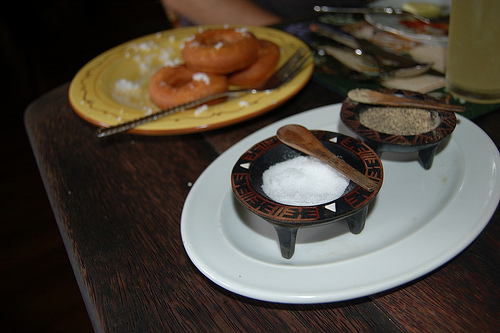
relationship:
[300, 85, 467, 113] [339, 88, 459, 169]
spoon on bowl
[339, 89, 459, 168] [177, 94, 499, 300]
bowl in plate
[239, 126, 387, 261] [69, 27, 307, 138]
bowl in plate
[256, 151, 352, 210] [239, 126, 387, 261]
salt in bowl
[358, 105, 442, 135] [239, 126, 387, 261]
pepper in bowl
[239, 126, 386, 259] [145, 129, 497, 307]
bowl sitting in plate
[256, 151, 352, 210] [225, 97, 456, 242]
salt sitting in bowl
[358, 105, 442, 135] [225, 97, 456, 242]
pepper sitting in bowl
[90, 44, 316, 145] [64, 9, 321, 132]
fork sitting in plate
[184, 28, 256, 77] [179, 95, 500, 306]
donut sitting in dish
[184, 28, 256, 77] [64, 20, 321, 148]
donut sitting in plate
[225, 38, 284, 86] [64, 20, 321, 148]
donut sitting in plate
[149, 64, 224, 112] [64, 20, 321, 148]
donut sitting in plate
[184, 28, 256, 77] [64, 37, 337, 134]
donut sitting on plate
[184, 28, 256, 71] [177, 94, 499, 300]
donut sitting on plate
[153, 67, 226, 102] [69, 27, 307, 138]
donut sitting on plate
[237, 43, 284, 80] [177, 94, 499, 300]
donut sitting on plate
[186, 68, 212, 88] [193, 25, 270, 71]
sugar on donut